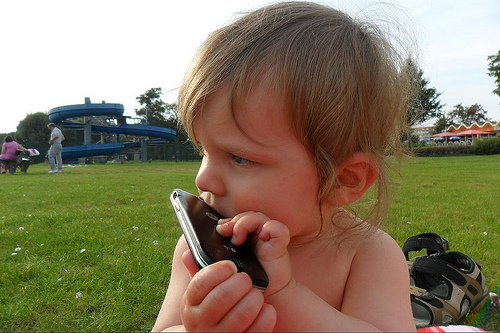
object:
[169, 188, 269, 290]
phone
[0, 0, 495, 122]
outside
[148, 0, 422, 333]
boy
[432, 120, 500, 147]
store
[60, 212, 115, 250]
grass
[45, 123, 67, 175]
man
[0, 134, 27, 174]
woman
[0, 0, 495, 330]
park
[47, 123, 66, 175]
adult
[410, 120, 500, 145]
canopy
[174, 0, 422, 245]
hair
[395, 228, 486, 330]
item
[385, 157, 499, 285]
ground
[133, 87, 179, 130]
tree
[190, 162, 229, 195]
nose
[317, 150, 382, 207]
ear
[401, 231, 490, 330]
sandal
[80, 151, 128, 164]
water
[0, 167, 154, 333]
area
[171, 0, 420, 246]
head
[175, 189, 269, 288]
plane